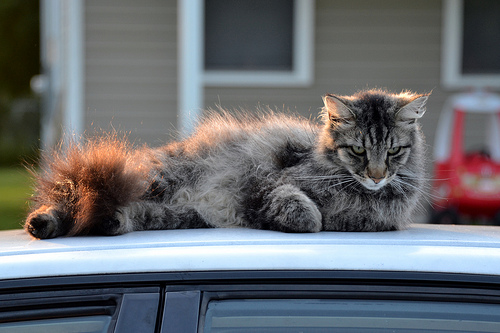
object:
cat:
[21, 88, 452, 239]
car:
[0, 223, 499, 332]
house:
[38, 0, 499, 227]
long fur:
[89, 94, 303, 153]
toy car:
[431, 90, 499, 198]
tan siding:
[98, 10, 158, 29]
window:
[174, 5, 316, 86]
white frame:
[261, 60, 316, 88]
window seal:
[201, 275, 387, 289]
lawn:
[7, 166, 29, 208]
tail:
[55, 143, 129, 198]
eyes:
[349, 136, 405, 155]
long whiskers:
[393, 173, 445, 208]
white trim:
[177, 37, 204, 120]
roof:
[16, 240, 494, 278]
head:
[321, 88, 433, 190]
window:
[329, 300, 438, 325]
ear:
[393, 86, 441, 125]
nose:
[367, 162, 391, 182]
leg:
[97, 193, 183, 237]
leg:
[22, 201, 60, 238]